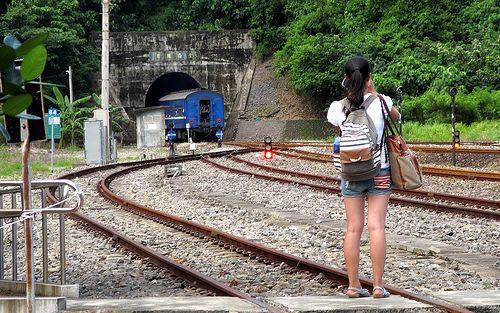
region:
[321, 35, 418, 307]
girl standing on train track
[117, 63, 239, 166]
blue train car going thru tunnel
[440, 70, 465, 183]
signal light on train track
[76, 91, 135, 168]
metal control boxes sitting beside train track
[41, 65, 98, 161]
green palm tree with long palms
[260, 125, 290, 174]
signal light on train track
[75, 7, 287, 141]
cement tunnel and bridge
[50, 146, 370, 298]
multi train tracks with gravel between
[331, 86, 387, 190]
brown and white striped backpack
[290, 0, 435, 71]
bright green leaves on trees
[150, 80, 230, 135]
Blue train coming out of the tunnel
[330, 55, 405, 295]
Girl standing on the tracks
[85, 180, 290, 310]
Rusted railroad tracks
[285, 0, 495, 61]
Tall, green trees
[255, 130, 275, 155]
Signal light on the left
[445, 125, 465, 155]
Signal light on the right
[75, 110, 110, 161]
Rectangle, grey utility box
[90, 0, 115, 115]
Tall, grey utility pole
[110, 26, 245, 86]
Black and grey train tunnel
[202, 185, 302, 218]
Rocks between the tracks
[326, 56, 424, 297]
A girl standing near train tracks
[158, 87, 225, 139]
A blue train car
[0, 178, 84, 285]
A silver metal railing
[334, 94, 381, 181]
A backpack worn by a girl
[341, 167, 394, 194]
Jean shorts worn by a girl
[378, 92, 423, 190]
A brown and gray shoulder bag being carried by a girl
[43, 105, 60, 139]
A green sign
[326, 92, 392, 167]
A white shirt worn by a girl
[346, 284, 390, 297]
A pair of sandals worn by a girl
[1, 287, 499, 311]
A concrete walkway a girl is standing on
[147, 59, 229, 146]
blue caboose going in a tunnel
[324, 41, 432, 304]
girl with a ponytail taking a picture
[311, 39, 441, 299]
girl in a white shirt and a backpack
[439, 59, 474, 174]
train signal with a yellow light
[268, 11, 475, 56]
green trees with lots of leaves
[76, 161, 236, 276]
train tracks and gravel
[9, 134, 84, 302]
metal fencing around a small tree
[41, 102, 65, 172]
green signal sign for a tree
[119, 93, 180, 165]
shack next to a blue train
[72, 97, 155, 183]
train transformer boxes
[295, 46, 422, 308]
a woman wearing a back pack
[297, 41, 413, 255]
a woman holding a brown bag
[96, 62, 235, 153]
blue train going through a tunnel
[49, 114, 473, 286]
several train tracks running together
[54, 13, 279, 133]
a concrete tunnel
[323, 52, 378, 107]
a woman with a pony tail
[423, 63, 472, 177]
a signal light for trains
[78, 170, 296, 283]
rocks on the ground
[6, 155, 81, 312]
a metal hand rail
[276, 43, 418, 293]
a woman using a cell phone